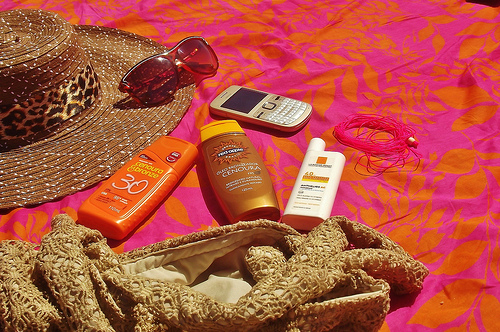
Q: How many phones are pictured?
A: One.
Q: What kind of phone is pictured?
A: A cell phone.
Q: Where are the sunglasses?
A: On the hat.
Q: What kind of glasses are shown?
A: Sunglasses.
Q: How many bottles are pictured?
A: Three.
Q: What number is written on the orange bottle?
A: 30.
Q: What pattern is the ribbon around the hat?
A: Animal print.